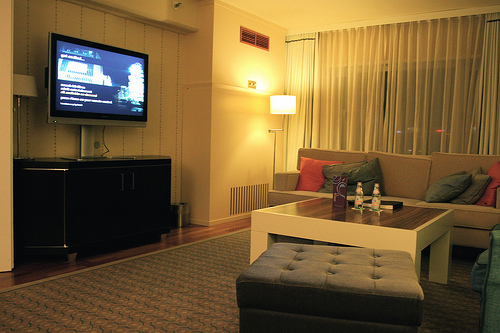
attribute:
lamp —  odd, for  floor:
[265, 83, 298, 173]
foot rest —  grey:
[234, 241, 424, 331]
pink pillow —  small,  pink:
[296, 156, 344, 195]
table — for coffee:
[250, 183, 461, 283]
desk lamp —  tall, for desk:
[11, 68, 43, 162]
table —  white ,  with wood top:
[256, 175, 466, 298]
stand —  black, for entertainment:
[16, 154, 173, 266]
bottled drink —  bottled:
[348, 177, 365, 212]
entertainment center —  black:
[11, 28, 193, 274]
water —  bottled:
[368, 182, 385, 214]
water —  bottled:
[353, 179, 367, 214]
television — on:
[45, 29, 147, 126]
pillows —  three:
[421, 163, 498, 206]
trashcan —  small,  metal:
[158, 206, 190, 236]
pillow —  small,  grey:
[316, 156, 368, 195]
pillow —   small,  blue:
[322, 154, 388, 197]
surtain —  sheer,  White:
[317, 22, 384, 154]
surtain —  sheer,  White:
[383, 14, 484, 156]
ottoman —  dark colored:
[232, 239, 427, 331]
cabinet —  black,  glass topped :
[13, 150, 173, 257]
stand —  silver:
[65, 127, 117, 159]